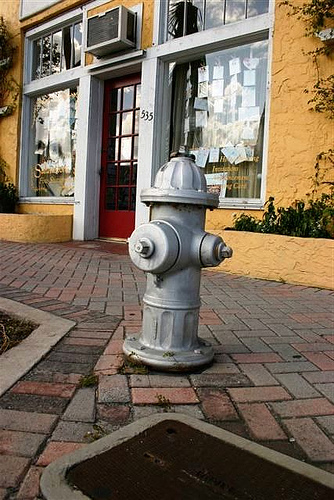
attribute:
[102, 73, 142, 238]
door — red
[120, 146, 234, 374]
hydrant — silver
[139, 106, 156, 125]
535 — black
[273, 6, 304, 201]
building — yellow, stucco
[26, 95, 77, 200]
window — big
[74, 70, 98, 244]
trim — white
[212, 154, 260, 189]
letters — gold